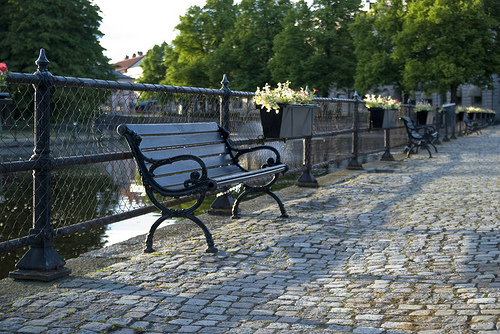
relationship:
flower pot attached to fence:
[260, 101, 317, 141] [3, 52, 493, 275]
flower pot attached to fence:
[368, 108, 403, 130] [3, 52, 493, 275]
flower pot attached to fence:
[412, 107, 436, 124] [3, 52, 493, 275]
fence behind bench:
[0, 64, 460, 284] [119, 114, 311, 254]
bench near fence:
[97, 100, 337, 279] [0, 51, 471, 290]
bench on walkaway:
[97, 100, 337, 279] [6, 125, 496, 332]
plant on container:
[251, 76, 323, 116] [259, 92, 324, 140]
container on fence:
[259, 92, 324, 140] [3, 52, 493, 275]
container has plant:
[260, 103, 312, 137] [250, 81, 323, 118]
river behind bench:
[2, 159, 157, 274] [117, 118, 289, 250]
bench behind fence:
[117, 118, 289, 250] [3, 52, 493, 275]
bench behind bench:
[117, 118, 289, 250] [401, 114, 437, 156]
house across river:
[97, 49, 182, 110] [9, 118, 484, 275]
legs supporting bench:
[141, 172, 290, 257] [115, 113, 299, 260]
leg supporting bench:
[138, 211, 223, 252] [115, 113, 299, 260]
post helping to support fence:
[26, 43, 75, 298] [156, 83, 387, 133]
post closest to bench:
[17, 52, 73, 289] [115, 113, 299, 260]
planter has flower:
[259, 99, 321, 137] [254, 75, 319, 112]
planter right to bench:
[259, 99, 321, 137] [126, 116, 289, 263]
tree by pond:
[1, 1, 115, 126] [50, 162, 140, 230]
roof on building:
[111, 52, 146, 72] [111, 50, 149, 94]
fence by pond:
[3, 48, 499, 258] [1, 125, 423, 277]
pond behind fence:
[0, 121, 465, 281] [3, 52, 493, 275]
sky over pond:
[87, 4, 197, 64] [2, 98, 397, 248]